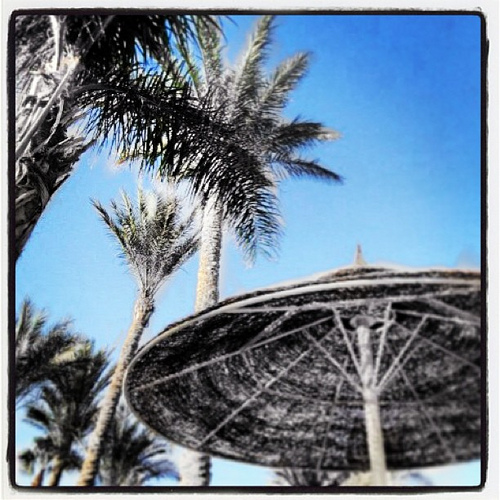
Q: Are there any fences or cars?
A: No, there are no fences or cars.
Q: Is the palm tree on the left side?
A: Yes, the palm tree is on the left of the image.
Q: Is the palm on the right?
A: No, the palm is on the left of the image.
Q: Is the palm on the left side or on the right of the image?
A: The palm is on the left of the image.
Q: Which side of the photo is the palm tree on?
A: The palm tree is on the left of the image.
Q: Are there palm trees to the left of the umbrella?
A: Yes, there is a palm tree to the left of the umbrella.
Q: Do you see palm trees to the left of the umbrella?
A: Yes, there is a palm tree to the left of the umbrella.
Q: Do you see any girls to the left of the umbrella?
A: No, there is a palm tree to the left of the umbrella.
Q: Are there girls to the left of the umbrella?
A: No, there is a palm tree to the left of the umbrella.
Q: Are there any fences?
A: No, there are no fences.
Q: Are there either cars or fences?
A: No, there are no fences or cars.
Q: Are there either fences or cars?
A: No, there are no fences or cars.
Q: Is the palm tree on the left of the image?
A: Yes, the palm tree is on the left of the image.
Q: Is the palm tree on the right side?
A: No, the palm tree is on the left of the image.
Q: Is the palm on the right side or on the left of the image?
A: The palm is on the left of the image.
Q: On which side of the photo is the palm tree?
A: The palm tree is on the left of the image.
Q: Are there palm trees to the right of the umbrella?
A: No, the palm tree is to the left of the umbrella.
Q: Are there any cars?
A: No, there are no cars.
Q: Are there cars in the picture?
A: No, there are no cars.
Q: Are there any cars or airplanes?
A: No, there are no cars or airplanes.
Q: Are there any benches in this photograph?
A: No, there are no benches.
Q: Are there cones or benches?
A: No, there are no benches or cones.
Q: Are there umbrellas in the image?
A: Yes, there is an umbrella.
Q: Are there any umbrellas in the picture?
A: Yes, there is an umbrella.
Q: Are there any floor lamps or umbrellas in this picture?
A: Yes, there is an umbrella.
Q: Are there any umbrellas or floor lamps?
A: Yes, there is an umbrella.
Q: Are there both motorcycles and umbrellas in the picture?
A: No, there is an umbrella but no motorcycles.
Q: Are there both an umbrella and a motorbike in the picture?
A: No, there is an umbrella but no motorcycles.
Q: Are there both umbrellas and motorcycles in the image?
A: No, there is an umbrella but no motorcycles.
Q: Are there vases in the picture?
A: No, there are no vases.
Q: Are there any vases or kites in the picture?
A: No, there are no vases or kites.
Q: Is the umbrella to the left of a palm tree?
A: No, the umbrella is to the right of a palm tree.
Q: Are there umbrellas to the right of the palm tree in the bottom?
A: Yes, there is an umbrella to the right of the palm tree.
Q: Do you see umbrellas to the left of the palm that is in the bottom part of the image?
A: No, the umbrella is to the right of the palm tree.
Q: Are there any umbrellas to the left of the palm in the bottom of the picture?
A: No, the umbrella is to the right of the palm tree.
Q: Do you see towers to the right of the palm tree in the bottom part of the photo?
A: No, there is an umbrella to the right of the palm.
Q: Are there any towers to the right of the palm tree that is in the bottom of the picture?
A: No, there is an umbrella to the right of the palm.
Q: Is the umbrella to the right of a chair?
A: No, the umbrella is to the right of the palm tree.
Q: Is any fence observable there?
A: No, there are no fences.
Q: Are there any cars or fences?
A: No, there are no fences or cars.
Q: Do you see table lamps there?
A: No, there are no table lamps.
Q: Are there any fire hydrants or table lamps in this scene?
A: No, there are no table lamps or fire hydrants.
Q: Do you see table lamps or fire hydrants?
A: No, there are no table lamps or fire hydrants.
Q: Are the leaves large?
A: Yes, the leaves are large.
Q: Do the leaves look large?
A: Yes, the leaves are large.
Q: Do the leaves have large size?
A: Yes, the leaves are large.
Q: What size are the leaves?
A: The leaves are large.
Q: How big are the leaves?
A: The leaves are large.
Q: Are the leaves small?
A: No, the leaves are large.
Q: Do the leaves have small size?
A: No, the leaves are large.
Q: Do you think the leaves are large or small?
A: The leaves are large.